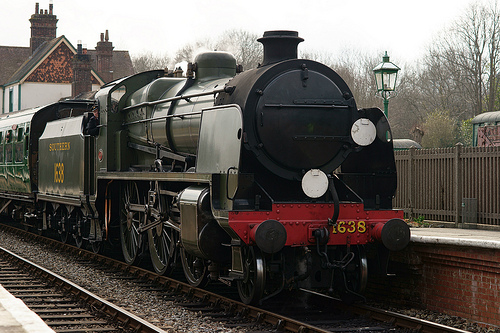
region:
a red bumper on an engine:
[228, 203, 406, 250]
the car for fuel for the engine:
[36, 116, 93, 249]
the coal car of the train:
[37, 111, 96, 248]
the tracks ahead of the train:
[258, 305, 470, 332]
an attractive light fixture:
[375, 51, 399, 117]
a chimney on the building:
[29, 1, 58, 44]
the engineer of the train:
[80, 100, 99, 136]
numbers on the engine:
[327, 218, 364, 235]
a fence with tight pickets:
[390, 140, 498, 222]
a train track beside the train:
[0, 246, 169, 331]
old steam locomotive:
[2, 30, 412, 307]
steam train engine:
[90, 29, 410, 299]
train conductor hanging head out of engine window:
[85, 105, 100, 133]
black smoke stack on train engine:
[257, 31, 303, 63]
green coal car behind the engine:
[40, 114, 95, 249]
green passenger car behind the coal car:
[2, 104, 88, 226]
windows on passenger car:
[1, 133, 25, 162]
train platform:
[403, 222, 498, 328]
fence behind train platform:
[397, 146, 497, 228]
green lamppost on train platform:
[373, 54, 398, 117]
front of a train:
[210, 56, 441, 314]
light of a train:
[299, 163, 334, 204]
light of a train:
[343, 106, 377, 146]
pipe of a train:
[246, 25, 331, 72]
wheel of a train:
[189, 185, 230, 282]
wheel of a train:
[293, 246, 393, 311]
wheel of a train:
[53, 198, 103, 260]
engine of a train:
[96, 31, 276, 183]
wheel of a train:
[3, 202, 30, 220]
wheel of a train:
[33, 205, 54, 232]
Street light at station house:
[375, 48, 398, 113]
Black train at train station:
[1, 31, 421, 311]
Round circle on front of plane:
[300, 168, 328, 198]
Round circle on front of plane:
[350, 118, 375, 146]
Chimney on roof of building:
[28, 1, 56, 57]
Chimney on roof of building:
[93, 30, 113, 71]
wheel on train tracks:
[176, 240, 211, 287]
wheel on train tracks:
[233, 240, 263, 302]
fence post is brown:
[453, 141, 464, 222]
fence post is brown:
[338, 145, 412, 303]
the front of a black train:
[101, 61, 396, 282]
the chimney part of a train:
[251, 25, 303, 66]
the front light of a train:
[281, 156, 341, 203]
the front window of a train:
[272, 69, 343, 114]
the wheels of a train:
[198, 248, 265, 302]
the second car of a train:
[21, 101, 109, 199]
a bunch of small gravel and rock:
[61, 262, 141, 317]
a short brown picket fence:
[400, 142, 494, 214]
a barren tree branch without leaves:
[451, 22, 498, 80]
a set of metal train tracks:
[24, 271, 109, 326]